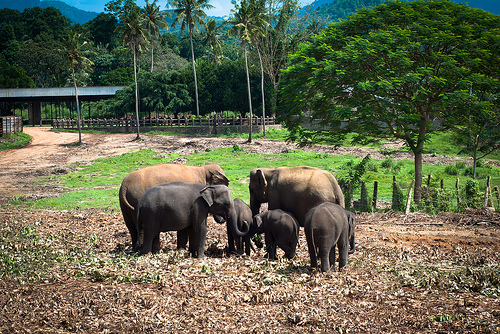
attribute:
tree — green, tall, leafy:
[275, 0, 498, 208]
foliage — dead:
[1, 203, 499, 331]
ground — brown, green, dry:
[1, 126, 498, 332]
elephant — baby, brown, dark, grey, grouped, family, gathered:
[253, 206, 302, 260]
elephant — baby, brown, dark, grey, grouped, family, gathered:
[229, 196, 257, 255]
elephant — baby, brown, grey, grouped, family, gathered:
[302, 201, 359, 275]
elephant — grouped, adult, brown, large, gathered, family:
[245, 165, 347, 215]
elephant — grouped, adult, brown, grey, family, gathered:
[132, 182, 249, 258]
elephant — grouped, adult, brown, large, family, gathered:
[118, 160, 230, 250]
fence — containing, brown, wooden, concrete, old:
[52, 112, 278, 129]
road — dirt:
[1, 121, 90, 166]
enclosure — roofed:
[0, 83, 127, 124]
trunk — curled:
[226, 206, 251, 241]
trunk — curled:
[347, 230, 357, 257]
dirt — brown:
[1, 126, 139, 200]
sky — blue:
[1, 0, 498, 20]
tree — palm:
[38, 31, 95, 146]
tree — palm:
[113, 0, 168, 147]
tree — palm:
[164, 0, 215, 121]